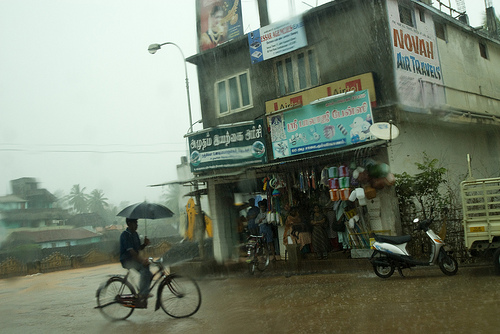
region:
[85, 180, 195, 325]
a man riding a bike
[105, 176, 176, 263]
a man holding a umbrella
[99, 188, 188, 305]
a man holding umbrella while riding a bike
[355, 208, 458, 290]
a scooter parked in front of a store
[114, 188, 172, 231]
a black umbrella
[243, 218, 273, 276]
a bike parked in front of a store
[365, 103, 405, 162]
a satellite dish on a building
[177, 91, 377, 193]
two signs on the front of a building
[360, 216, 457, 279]
a silver scooter parked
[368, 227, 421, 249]
a black seat on a scooter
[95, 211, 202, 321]
man riding a bicycle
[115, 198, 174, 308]
man holding an umbrella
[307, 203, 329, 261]
girl standing in front of store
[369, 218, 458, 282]
moped parked on the street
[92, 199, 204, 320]
man riding bicycle under de rain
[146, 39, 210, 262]
post light on the sidewalk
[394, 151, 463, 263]
bushes next to scooter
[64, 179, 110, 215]
palm trees in the distance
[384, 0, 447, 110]
advertisement on wall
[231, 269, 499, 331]
raindrops on the street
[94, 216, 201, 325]
a person riding his bicycle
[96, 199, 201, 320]
person holding an umbrella while riding the bicycle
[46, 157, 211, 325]
a person riding the bicycle while raining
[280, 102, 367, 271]
plastic buckets hanging in front of the shop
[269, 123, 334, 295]
people waiting in the shop to stay to avoid getting wet from rain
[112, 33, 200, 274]
a tall lamp post on the road side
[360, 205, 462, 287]
a scooter parked outside in the rain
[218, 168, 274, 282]
a bicycle parked in front of a shop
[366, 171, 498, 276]
the scooter is parked behind another vehicle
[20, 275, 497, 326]
the path is covered with rain water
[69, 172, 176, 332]
Man on a bicycle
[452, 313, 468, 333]
Small droplets of water on the pavement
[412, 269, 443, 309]
Small droplets of water on the pavement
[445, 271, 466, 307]
Small droplets of water on the pavement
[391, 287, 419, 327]
Small droplets of water on the pavement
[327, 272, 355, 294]
Small droplets of water on the pavement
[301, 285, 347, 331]
Small droplets of water on the pavement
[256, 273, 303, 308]
Small droplets of water on the pavement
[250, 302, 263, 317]
Small droplets of water on the pavement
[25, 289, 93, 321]
Small droplets of water on the pavement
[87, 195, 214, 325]
Man riding his bike.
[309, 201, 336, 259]
Little girl wearing brown and black striped dress.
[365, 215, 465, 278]
White motorbike park outside of store.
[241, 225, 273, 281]
Red bike parked in front of store.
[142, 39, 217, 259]
Street light outside of store.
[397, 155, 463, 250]
Large plants on side of building.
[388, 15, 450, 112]
'Novah' ad painted on side of building.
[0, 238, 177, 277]
Small wooden fences in background.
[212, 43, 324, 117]
Seven white windows on front of building.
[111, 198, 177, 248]
Black umbrella held by a man.